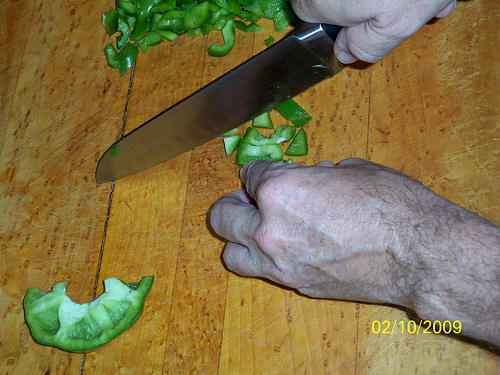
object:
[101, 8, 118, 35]
paprika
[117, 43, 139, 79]
paprica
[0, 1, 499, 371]
board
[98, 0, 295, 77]
cuts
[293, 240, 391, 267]
veins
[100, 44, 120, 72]
papricca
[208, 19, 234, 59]
papricca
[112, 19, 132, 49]
papricca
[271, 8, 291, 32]
papricca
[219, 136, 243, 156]
vegetables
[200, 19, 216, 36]
pepper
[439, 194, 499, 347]
arm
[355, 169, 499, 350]
hair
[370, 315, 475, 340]
stamp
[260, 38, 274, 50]
pepper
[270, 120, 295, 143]
pepper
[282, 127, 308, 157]
pepper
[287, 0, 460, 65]
hand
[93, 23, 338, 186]
knife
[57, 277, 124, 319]
membrane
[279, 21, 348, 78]
handle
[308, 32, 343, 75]
trim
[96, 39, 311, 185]
blade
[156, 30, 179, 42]
pepper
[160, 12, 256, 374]
block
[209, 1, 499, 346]
man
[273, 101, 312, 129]
vegetable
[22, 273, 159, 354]
vegetable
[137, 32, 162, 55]
vegetable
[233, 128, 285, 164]
pepper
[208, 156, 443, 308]
left hand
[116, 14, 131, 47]
pepper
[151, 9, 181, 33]
pepper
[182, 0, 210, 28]
pepper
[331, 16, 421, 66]
thumb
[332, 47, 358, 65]
nail